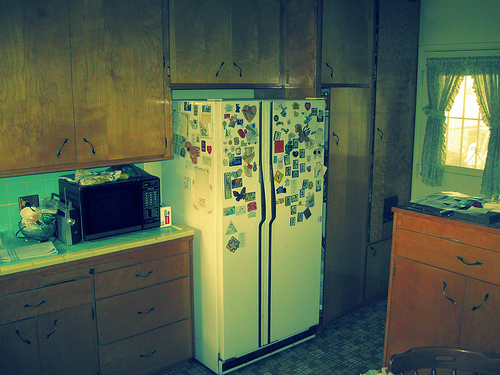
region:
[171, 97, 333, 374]
maganet covered side by side refridgerator freezer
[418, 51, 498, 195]
ruffled edged cafe curtains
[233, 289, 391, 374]
floor covered in linoleum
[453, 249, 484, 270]
a drawer pull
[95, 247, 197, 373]
stack of three drawers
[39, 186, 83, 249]
a radio on the counter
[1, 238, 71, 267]
a white kitchen towel with stripes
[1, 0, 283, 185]
overhead cupboard doors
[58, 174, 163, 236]
a microwave oven on counter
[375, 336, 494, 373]
top of a wooden chair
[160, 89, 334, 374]
A refrigerator covered in magnets.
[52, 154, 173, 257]
a black microwave oven.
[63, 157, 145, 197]
a pair of oven mitts.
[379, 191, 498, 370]
a black kitchen counter top.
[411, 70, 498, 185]
a window in a kitchen.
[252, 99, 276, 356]
handles on a refrigerator door.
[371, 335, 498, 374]
a trash can in a kitchen.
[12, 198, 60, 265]
a bag on a counter top.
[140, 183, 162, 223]
a microwave control panel.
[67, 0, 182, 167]
a wooden kitchen cabinet.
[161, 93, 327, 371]
refrigerator with plenty magnets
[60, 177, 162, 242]
black microwave on counter top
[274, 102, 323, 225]
magnets on fridge door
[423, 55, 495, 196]
curtains hanging in the kitchen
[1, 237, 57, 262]
kitchen rag for dishes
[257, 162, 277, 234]
two handles for refrigerator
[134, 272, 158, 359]
black hardware handles for drawers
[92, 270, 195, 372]
drawers for cooking utensils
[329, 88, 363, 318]
pantry to store spices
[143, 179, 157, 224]
operating functions for microwave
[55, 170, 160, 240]
Black microwave on counter top.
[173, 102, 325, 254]
Lots of magnets on refrigerator.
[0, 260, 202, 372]
Brown wooden cabinet drawers.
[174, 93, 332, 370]
Side by side white refrigerator.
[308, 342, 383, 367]
Brown and tan tile floor.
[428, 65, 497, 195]
Tan lace window curtains.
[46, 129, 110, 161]
Black wrought iron cabinet handles.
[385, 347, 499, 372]
Brown wooden kitchen chair.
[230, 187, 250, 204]
Butterfly shaped refrigerator magnet.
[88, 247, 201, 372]
Three kitchen drawers.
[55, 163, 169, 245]
a black microwave on the counter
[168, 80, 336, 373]
a white refrigerator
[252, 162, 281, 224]
the handles of the refrigerator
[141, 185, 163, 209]
the keypad on the microwave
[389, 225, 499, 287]
a brown drawer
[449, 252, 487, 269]
a handle on the drawer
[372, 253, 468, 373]
a brown wooden cabinet door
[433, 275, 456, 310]
a handle on the cabinet door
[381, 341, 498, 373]
a brown wooden chair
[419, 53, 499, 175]
a window in the room